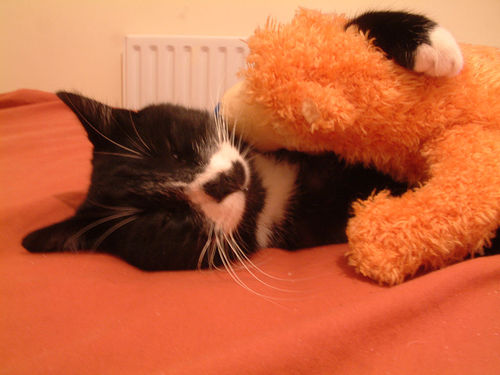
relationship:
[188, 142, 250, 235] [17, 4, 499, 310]
white markings on cat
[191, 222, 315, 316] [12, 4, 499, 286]
whiskers on cat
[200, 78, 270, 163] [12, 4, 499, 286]
whiskers on cat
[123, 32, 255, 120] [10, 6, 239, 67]
a/c on wall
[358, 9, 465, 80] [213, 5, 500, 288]
paw holding onto brown toy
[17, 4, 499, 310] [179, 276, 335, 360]
cat laying on blanket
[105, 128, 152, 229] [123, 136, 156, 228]
white whiskers on eyebrows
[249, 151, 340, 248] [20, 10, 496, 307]
chest on cat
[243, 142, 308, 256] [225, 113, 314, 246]
markings on neck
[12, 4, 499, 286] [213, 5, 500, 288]
cat hugging brown toy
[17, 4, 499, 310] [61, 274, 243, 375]
cat on bed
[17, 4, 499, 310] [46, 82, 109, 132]
cat has ears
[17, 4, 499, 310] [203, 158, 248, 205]
cat has nose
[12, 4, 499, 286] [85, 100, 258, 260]
cat has face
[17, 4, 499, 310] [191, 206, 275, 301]
cat has whiskers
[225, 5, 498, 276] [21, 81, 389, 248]
brown toy on cat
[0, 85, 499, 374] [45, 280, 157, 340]
blanket on bed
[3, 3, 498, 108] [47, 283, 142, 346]
tan wall behind bed